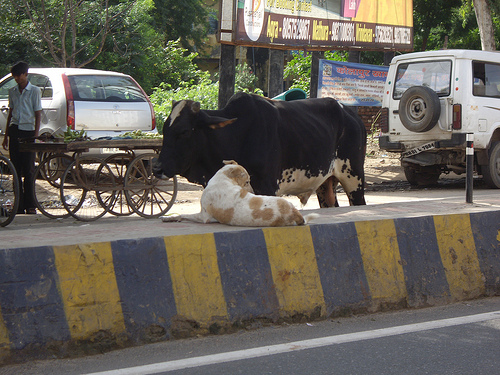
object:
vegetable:
[59, 126, 90, 142]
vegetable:
[119, 129, 163, 139]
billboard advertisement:
[219, 0, 412, 50]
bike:
[19, 139, 177, 221]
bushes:
[147, 81, 220, 117]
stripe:
[53, 242, 130, 348]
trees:
[0, 2, 171, 68]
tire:
[397, 85, 441, 133]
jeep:
[378, 48, 498, 190]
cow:
[151, 91, 366, 208]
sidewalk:
[2, 178, 500, 375]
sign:
[318, 58, 389, 107]